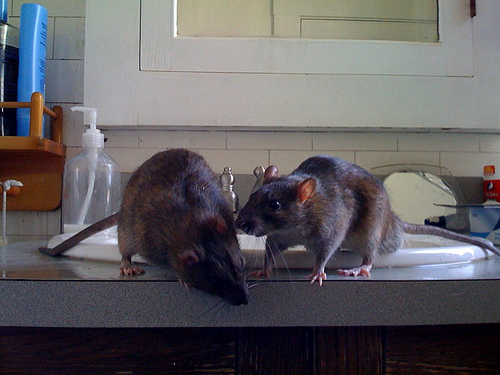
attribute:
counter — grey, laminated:
[34, 265, 113, 317]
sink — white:
[414, 230, 469, 263]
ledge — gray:
[274, 278, 404, 318]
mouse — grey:
[211, 152, 426, 288]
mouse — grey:
[117, 147, 257, 277]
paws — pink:
[239, 264, 402, 303]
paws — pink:
[106, 240, 192, 294]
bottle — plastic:
[54, 100, 194, 245]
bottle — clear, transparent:
[60, 106, 117, 241]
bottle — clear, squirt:
[59, 107, 116, 228]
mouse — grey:
[240, 153, 484, 295]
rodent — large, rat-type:
[34, 150, 252, 306]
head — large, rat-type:
[174, 234, 261, 316]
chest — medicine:
[86, 10, 484, 120]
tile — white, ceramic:
[104, 142, 172, 172]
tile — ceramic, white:
[50, 104, 140, 150]